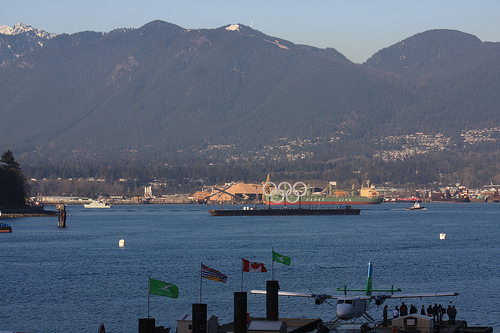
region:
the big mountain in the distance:
[1, 19, 498, 185]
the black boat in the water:
[206, 180, 360, 215]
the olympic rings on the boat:
[263, 181, 308, 203]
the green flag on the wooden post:
[146, 275, 178, 315]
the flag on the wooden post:
[199, 262, 227, 303]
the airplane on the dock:
[249, 258, 459, 323]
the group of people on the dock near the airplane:
[381, 300, 457, 325]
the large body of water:
[0, 202, 499, 329]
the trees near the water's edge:
[0, 148, 27, 215]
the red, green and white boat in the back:
[263, 183, 383, 204]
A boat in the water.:
[186, 163, 389, 227]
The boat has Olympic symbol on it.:
[251, 172, 314, 202]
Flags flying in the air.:
[138, 263, 219, 304]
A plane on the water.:
[309, 247, 416, 318]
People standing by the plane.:
[380, 285, 480, 319]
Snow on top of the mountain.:
[196, 23, 307, 53]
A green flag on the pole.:
[267, 233, 288, 284]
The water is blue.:
[77, 184, 259, 267]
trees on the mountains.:
[47, 62, 254, 152]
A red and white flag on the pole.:
[232, 243, 267, 288]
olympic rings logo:
[245, 182, 322, 214]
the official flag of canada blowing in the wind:
[234, 253, 269, 279]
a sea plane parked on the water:
[240, 242, 463, 322]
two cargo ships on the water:
[202, 185, 397, 227]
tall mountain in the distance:
[5, 3, 499, 192]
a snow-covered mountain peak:
[2, 16, 62, 53]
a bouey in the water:
[107, 231, 141, 255]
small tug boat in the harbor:
[408, 197, 432, 217]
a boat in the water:
[77, 193, 118, 215]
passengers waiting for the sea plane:
[375, 293, 470, 327]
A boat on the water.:
[197, 163, 370, 241]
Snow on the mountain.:
[7, 18, 87, 48]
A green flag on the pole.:
[131, 261, 183, 315]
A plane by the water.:
[293, 267, 443, 323]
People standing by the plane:
[381, 284, 463, 331]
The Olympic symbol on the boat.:
[255, 163, 312, 205]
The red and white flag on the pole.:
[239, 250, 264, 290]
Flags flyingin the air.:
[132, 249, 314, 294]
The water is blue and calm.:
[93, 203, 265, 255]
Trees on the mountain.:
[139, 136, 251, 185]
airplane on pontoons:
[251, 261, 471, 321]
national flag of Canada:
[230, 258, 269, 276]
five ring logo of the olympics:
[264, 178, 307, 205]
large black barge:
[207, 200, 365, 217]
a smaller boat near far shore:
[403, 194, 428, 216]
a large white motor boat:
[76, 195, 116, 215]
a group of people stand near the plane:
[379, 295, 461, 322]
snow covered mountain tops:
[1, 10, 288, 62]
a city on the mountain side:
[178, 130, 498, 198]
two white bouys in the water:
[108, 228, 451, 252]